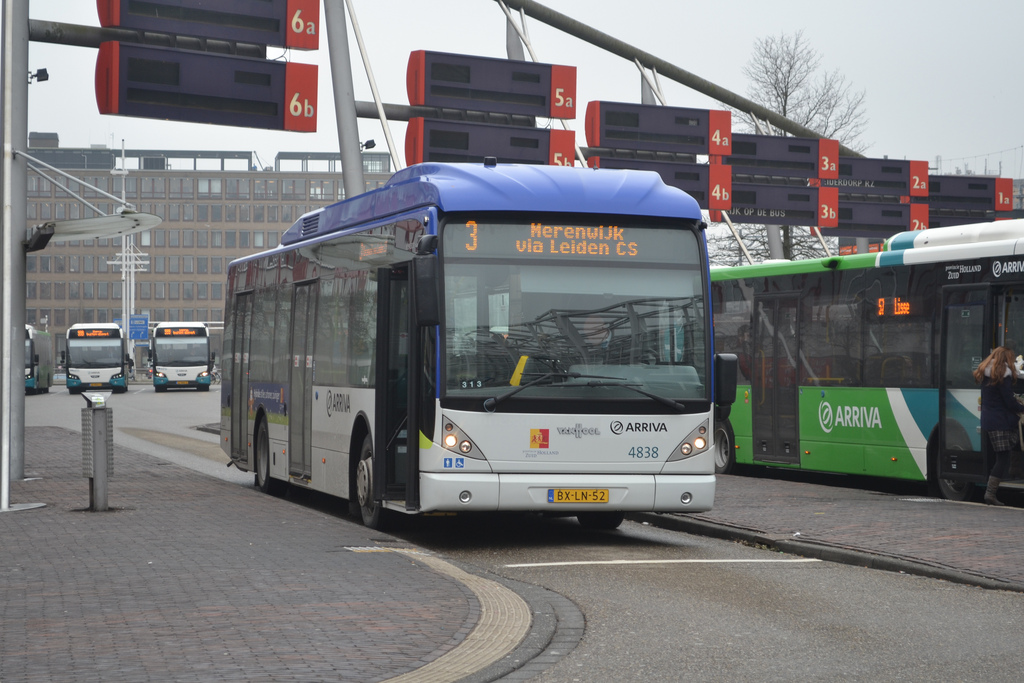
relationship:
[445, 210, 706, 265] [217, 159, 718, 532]
display on bus